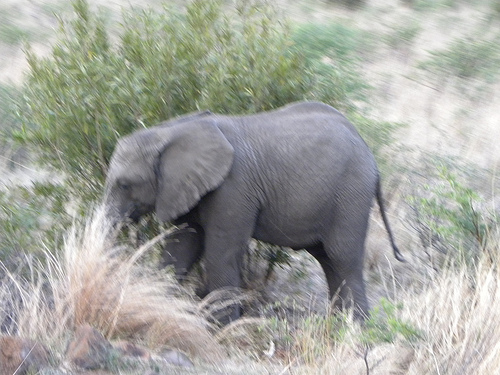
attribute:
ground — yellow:
[2, 188, 500, 370]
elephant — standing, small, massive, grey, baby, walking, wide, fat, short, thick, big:
[103, 101, 374, 318]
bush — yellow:
[4, 219, 217, 370]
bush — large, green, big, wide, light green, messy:
[15, 3, 355, 100]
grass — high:
[45, 155, 229, 368]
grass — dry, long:
[39, 172, 313, 372]